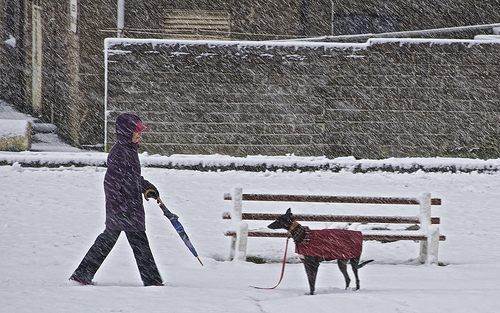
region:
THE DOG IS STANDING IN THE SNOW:
[243, 200, 369, 306]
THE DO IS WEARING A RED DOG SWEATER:
[295, 220, 378, 271]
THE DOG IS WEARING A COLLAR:
[287, 220, 293, 233]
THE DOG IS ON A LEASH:
[241, 235, 296, 298]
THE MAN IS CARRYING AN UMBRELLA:
[145, 183, 205, 275]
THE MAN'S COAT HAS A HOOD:
[85, 95, 163, 230]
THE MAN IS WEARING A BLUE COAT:
[98, 97, 154, 233]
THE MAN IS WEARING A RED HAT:
[125, 117, 150, 132]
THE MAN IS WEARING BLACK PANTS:
[45, 217, 166, 302]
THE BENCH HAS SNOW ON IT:
[203, 163, 469, 280]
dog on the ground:
[254, 181, 399, 296]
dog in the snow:
[241, 188, 383, 307]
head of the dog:
[258, 199, 305, 248]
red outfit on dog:
[292, 215, 372, 278]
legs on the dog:
[283, 260, 370, 292]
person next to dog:
[48, 84, 222, 266]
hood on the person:
[101, 98, 161, 162]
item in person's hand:
[142, 178, 210, 256]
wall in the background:
[249, 74, 333, 128]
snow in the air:
[16, 9, 111, 101]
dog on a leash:
[268, 204, 385, 297]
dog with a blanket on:
[262, 202, 378, 295]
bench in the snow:
[208, 161, 458, 274]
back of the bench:
[217, 191, 447, 226]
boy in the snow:
[66, 104, 177, 309]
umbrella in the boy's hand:
[133, 178, 204, 285]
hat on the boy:
[110, 116, 152, 137]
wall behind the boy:
[90, 35, 494, 180]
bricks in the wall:
[93, 38, 495, 168]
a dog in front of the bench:
[250, 204, 368, 301]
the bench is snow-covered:
[216, 186, 441, 267]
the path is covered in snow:
[20, 245, 497, 307]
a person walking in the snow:
[67, 102, 205, 288]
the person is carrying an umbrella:
[135, 174, 212, 276]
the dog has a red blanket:
[303, 223, 368, 263]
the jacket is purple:
[105, 106, 147, 236]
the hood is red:
[130, 120, 148, 133]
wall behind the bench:
[77, 14, 498, 159]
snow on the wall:
[105, 30, 498, 54]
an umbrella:
[153, 203, 221, 265]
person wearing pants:
[88, 219, 166, 296]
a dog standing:
[259, 210, 386, 292]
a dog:
[263, 209, 371, 296]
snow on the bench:
[223, 188, 249, 254]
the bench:
[363, 187, 423, 235]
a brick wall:
[172, 64, 306, 133]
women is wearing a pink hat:
[138, 120, 149, 136]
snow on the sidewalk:
[39, 140, 92, 163]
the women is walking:
[73, 113, 175, 286]